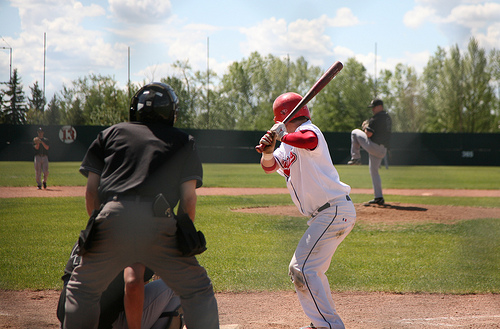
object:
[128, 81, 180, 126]
hat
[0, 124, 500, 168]
green fence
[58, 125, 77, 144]
logo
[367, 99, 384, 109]
hat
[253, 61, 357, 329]
batter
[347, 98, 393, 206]
pitcher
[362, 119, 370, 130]
ball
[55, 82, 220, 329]
player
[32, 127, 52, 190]
player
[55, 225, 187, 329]
player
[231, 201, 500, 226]
dirt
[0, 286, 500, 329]
dirt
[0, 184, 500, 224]
dirt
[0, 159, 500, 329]
field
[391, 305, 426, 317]
patch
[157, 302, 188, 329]
tall lamp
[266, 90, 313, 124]
helmet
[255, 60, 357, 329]
ball player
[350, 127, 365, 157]
leg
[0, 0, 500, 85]
sky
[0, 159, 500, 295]
green grass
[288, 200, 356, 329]
pants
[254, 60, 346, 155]
bat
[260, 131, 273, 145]
fingers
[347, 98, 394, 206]
black bag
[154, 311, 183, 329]
protection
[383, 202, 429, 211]
shadow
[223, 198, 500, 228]
mound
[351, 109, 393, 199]
uniform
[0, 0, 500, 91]
cloud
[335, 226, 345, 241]
dirt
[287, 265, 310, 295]
dirt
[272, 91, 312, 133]
batter's head